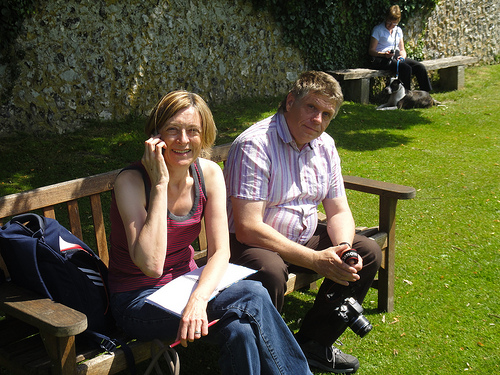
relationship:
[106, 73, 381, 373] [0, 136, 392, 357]
people are sitting on bench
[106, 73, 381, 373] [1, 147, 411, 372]
people sitting on bench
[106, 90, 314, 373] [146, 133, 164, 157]
people on cell phone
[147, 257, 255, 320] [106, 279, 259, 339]
book on lap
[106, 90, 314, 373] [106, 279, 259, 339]
people has lap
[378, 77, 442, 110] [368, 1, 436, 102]
dog beside woman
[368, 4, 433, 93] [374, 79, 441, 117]
person sitting with dog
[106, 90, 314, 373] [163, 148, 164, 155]
people on cellphone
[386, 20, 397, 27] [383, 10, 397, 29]
glasses on woman's face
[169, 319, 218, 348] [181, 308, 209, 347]
pencil in hand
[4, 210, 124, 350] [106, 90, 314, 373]
back pack by people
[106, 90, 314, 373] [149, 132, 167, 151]
people holding cell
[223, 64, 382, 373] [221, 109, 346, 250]
man wearing shirt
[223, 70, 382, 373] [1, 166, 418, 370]
man sitting on bench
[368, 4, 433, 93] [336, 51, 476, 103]
person sitting on bench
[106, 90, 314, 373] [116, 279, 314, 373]
people wearing jeans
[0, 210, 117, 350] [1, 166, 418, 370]
back pack on bench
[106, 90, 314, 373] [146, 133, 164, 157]
people talking on cell phone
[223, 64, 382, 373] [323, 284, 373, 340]
man holding camera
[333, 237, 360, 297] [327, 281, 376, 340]
strap on camera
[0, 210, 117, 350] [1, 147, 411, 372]
back pack on bench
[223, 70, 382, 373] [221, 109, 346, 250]
man wearing shirt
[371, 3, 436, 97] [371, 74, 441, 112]
person has a dog